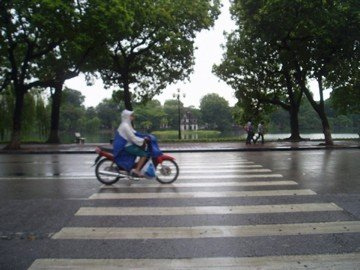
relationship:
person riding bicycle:
[101, 108, 148, 200] [90, 134, 180, 185]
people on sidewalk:
[253, 120, 269, 144] [1, 139, 359, 153]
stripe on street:
[87, 188, 319, 202] [16, 148, 356, 241]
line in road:
[72, 202, 343, 217] [1, 148, 360, 269]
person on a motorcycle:
[111, 108, 150, 178] [95, 136, 180, 188]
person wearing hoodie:
[111, 108, 150, 178] [118, 109, 144, 146]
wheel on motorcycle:
[94, 153, 120, 189] [90, 135, 183, 187]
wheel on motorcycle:
[152, 155, 181, 185] [90, 135, 183, 187]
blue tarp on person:
[110, 132, 126, 158] [111, 108, 150, 178]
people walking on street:
[253, 120, 269, 144] [201, 129, 324, 163]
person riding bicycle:
[111, 108, 150, 178] [90, 134, 180, 185]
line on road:
[72, 202, 343, 217] [1, 148, 360, 269]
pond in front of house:
[238, 131, 358, 139] [179, 109, 201, 130]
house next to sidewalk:
[179, 109, 201, 130] [1, 139, 359, 153]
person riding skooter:
[111, 108, 150, 178] [94, 144, 179, 187]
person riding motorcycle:
[111, 108, 150, 178] [87, 128, 181, 189]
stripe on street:
[77, 195, 349, 211] [14, 143, 351, 268]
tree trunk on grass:
[47, 82, 68, 142] [7, 139, 92, 143]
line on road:
[72, 202, 343, 217] [7, 184, 64, 218]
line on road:
[72, 202, 343, 217] [5, 155, 332, 268]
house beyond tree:
[179, 112, 201, 130] [210, 24, 313, 143]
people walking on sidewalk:
[245, 118, 265, 144] [20, 143, 349, 152]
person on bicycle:
[111, 108, 150, 178] [90, 134, 180, 185]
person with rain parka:
[111, 108, 150, 178] [111, 109, 147, 174]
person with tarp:
[111, 108, 150, 178] [137, 129, 161, 159]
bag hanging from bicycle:
[144, 163, 156, 181] [90, 134, 180, 185]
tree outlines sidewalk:
[221, 38, 340, 138] [112, 101, 304, 138]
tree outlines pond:
[221, 38, 340, 138] [244, 119, 349, 137]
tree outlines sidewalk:
[94, 14, 170, 139] [112, 101, 304, 138]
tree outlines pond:
[94, 14, 170, 139] [244, 119, 349, 137]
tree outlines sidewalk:
[22, 31, 99, 147] [112, 101, 304, 138]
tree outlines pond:
[22, 31, 99, 147] [244, 119, 349, 137]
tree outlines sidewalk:
[0, 16, 23, 146] [112, 101, 304, 138]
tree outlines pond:
[0, 16, 23, 146] [244, 119, 349, 137]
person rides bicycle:
[111, 108, 150, 178] [90, 137, 177, 184]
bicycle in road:
[90, 137, 177, 184] [1, 148, 360, 269]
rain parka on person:
[104, 104, 147, 152] [106, 106, 151, 179]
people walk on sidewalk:
[253, 120, 269, 144] [4, 129, 358, 155]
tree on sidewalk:
[210, 24, 313, 143] [228, 138, 343, 150]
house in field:
[179, 109, 201, 130] [141, 122, 227, 154]